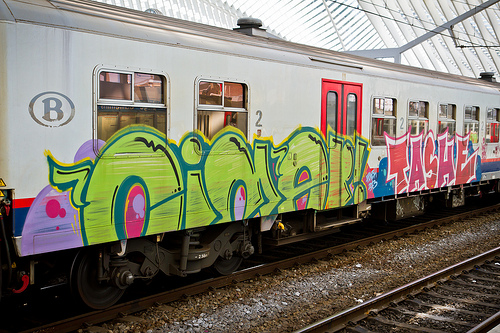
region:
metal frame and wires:
[353, 1, 494, 61]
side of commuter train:
[0, 8, 495, 295]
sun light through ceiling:
[203, 1, 370, 38]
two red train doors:
[320, 79, 362, 204]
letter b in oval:
[26, 90, 76, 128]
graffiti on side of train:
[25, 132, 488, 259]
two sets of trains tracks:
[83, 209, 498, 327]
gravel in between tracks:
[171, 214, 494, 331]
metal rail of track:
[303, 246, 497, 331]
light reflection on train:
[199, 79, 246, 145]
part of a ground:
[345, 247, 375, 277]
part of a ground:
[258, 263, 301, 305]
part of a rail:
[415, 248, 450, 289]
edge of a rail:
[376, 268, 402, 303]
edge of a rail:
[411, 260, 436, 295]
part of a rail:
[385, 215, 402, 233]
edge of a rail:
[396, 278, 416, 302]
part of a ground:
[368, 255, 392, 282]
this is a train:
[71, 38, 374, 223]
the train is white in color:
[255, 64, 315, 116]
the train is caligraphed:
[244, 138, 341, 218]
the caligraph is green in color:
[269, 141, 337, 201]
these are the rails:
[404, 247, 470, 320]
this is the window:
[205, 78, 247, 114]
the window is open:
[225, 80, 241, 100]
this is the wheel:
[81, 239, 153, 295]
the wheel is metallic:
[76, 248, 124, 291]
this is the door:
[320, 82, 355, 148]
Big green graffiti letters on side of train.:
[90, 132, 305, 224]